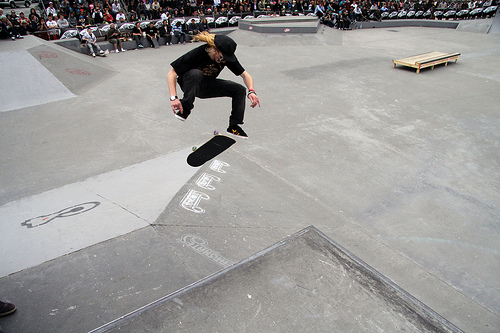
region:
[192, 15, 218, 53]
girl has blonde hair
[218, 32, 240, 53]
girl has black cap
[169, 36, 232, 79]
girl has black shirt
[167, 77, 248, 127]
girl has black pants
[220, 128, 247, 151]
black and white shoes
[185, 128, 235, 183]
black skateboard is flipping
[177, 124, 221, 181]
white wheels on board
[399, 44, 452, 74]
brown rail on concrete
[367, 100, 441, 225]
concrete is light brown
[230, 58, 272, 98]
girl is wearing bracelets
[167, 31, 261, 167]
Skateboarder doing a trick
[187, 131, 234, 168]
Black skateboard in air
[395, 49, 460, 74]
Wooden platform in skate ramp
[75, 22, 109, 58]
Spectator sitting on bench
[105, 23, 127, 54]
Person sitting on bench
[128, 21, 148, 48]
Person sitting on bench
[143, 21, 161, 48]
Person sitting on bench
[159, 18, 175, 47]
Person sitting on bench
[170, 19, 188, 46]
Person sitting on bench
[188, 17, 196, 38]
Person sitting on bench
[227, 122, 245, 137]
this is the shoe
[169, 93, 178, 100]
this is a watch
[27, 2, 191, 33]
these are the people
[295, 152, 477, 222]
this is the floor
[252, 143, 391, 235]
the floor is tarmacked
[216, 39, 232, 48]
this is a cap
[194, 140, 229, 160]
this is a skating board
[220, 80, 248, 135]
this is a leg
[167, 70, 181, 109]
this is a hand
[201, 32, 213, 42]
this is the hair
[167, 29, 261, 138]
the skateboarder in mid air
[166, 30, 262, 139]
the skateboarder above the skateboard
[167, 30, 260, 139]
the skateboarder above ground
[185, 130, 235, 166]
the skateboard in mid air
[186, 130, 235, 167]
the skateboard above ground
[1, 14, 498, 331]
the skate park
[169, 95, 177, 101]
the watch on the man's arm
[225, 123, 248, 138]
the shoe on the man's foot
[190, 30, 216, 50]
the long hair on the man's head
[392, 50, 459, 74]
the wood object